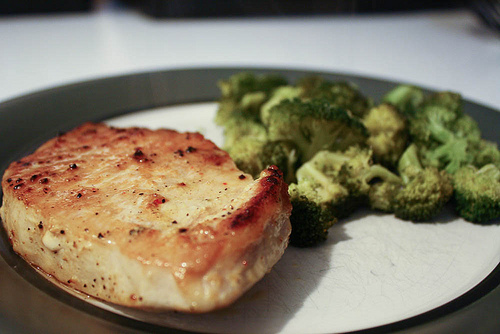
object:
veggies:
[229, 68, 326, 150]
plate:
[338, 227, 489, 321]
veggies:
[342, 84, 418, 152]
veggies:
[296, 142, 367, 232]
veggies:
[387, 151, 495, 224]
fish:
[32, 124, 271, 311]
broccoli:
[269, 98, 361, 157]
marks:
[317, 244, 359, 289]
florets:
[304, 96, 335, 119]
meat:
[19, 163, 235, 262]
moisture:
[128, 244, 215, 280]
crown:
[293, 193, 328, 249]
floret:
[287, 183, 313, 226]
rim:
[453, 291, 492, 328]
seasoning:
[68, 145, 155, 179]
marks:
[227, 164, 288, 214]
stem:
[296, 129, 336, 159]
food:
[58, 72, 477, 287]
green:
[322, 108, 396, 165]